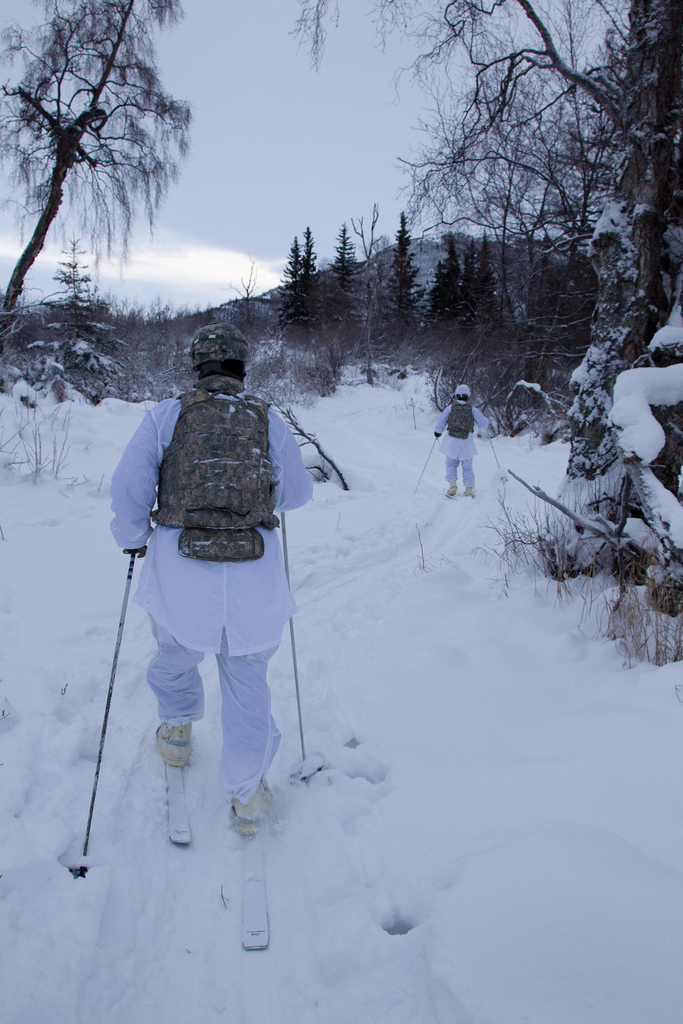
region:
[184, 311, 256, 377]
A camouflage hat on a human head.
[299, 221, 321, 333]
A tall green needle filled pine tree.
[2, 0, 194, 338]
A tall tree with lots of leaves.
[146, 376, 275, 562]
A backpack on a person's back.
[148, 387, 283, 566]
A camouflaged colored back pack.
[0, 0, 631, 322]
A hazy gray cloud filled sky.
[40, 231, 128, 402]
A tree sitting in the middle of a forest.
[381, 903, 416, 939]
A foot print in the snow.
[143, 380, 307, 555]
THE MAN'S BACKPACK IS CAMOUFLAGE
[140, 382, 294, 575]
THE MAN IS WEARING A BACKPACK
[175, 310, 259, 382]
THE MAN'S HELMET IS CAMOUFLAGE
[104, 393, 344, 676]
THE MAN IS WEARING A JACKET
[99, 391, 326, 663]
THE MAN'S JACKET IS WHITE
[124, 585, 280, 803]
THE MAN IS WEARING WHITE PANTS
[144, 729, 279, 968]
THE MAN IS WEARING SKIS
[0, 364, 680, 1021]
THE GROUND IS COVERED IN COLD WHITE SNOW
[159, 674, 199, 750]
leg of the person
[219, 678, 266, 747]
leg of the person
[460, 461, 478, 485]
leg of the person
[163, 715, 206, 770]
foot of the person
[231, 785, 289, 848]
foot of the person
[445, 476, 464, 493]
foot of the person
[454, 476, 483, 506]
foot of the person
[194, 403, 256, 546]
backpack on the back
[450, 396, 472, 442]
backpack on the back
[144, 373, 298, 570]
THE MAN IS WEARING A BACK PACK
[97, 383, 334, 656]
THE MAN IS WEARING A WHITE COAT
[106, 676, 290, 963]
THE MAN IS ON SKIS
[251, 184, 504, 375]
THE PATCH OF GREEN TREES ARE EVERGREENS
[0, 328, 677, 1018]
THE GROUND IS COVERED IN WHITE SNOW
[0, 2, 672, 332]
THE SKY IS HAZY AND GREY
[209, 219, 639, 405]
THE MOUNTAIN IS IN THE DISTANCE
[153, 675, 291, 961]
Person on skis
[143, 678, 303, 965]
Person is on skis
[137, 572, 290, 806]
Person wearing pants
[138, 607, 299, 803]
Person is wearing pants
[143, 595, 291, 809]
Person is wearing white pants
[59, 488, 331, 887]
Person holding ski poles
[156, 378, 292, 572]
Person is wearing a camouflage patterned backpack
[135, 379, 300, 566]
Person wearing a camouflage patterned backpack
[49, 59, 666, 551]
a scene in a forest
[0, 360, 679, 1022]
snow on the ground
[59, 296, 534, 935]
couple of skiers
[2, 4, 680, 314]
a gray sky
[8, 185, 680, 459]
some green trees in the background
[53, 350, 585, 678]
tracks in the snow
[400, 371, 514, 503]
front man on skis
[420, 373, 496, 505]
first man skiing in snow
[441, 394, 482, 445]
first mans vest is green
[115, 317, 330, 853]
second man on skis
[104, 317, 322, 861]
second man skiing in snow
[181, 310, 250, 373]
man wearing camo cap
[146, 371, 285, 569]
second mans vest is camo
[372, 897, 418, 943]
small hole in snow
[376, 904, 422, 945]
a hole in the snow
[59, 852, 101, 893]
the end of a ski pole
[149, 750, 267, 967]
pair of white skis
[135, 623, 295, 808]
person's white ski pants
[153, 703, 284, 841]
blue and white boots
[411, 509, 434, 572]
a twig in the snow